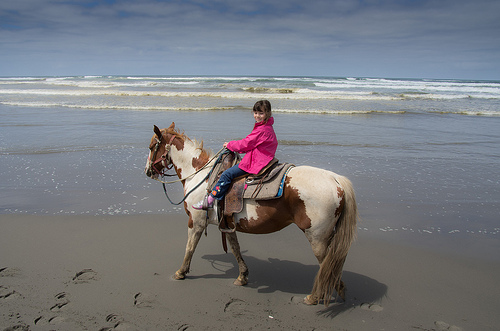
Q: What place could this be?
A: It is a lake.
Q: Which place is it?
A: It is a lake.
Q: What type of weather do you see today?
A: It is cloudy.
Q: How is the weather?
A: It is cloudy.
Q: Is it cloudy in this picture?
A: Yes, it is cloudy.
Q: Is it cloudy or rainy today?
A: It is cloudy.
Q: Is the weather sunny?
A: No, it is cloudy.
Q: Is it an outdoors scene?
A: Yes, it is outdoors.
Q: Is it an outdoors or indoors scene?
A: It is outdoors.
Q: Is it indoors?
A: No, it is outdoors.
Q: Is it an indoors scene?
A: No, it is outdoors.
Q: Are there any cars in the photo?
A: No, there are no cars.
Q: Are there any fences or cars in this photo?
A: No, there are no cars or fences.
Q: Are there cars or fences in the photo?
A: No, there are no cars or fences.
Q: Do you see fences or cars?
A: No, there are no cars or fences.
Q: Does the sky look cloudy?
A: Yes, the sky is cloudy.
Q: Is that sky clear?
A: No, the sky is cloudy.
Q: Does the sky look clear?
A: No, the sky is cloudy.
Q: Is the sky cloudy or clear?
A: The sky is cloudy.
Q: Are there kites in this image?
A: No, there are no kites.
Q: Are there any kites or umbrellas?
A: No, there are no kites or umbrellas.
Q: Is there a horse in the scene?
A: Yes, there is a horse.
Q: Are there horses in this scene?
A: Yes, there is a horse.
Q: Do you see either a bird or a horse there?
A: Yes, there is a horse.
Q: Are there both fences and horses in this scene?
A: No, there is a horse but no fences.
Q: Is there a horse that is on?
A: Yes, there is a horse that is on.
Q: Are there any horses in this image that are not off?
A: Yes, there is a horse that is on.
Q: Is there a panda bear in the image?
A: No, there are no panda bears.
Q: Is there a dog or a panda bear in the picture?
A: No, there are no panda bears or dogs.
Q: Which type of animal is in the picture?
A: The animal is a horse.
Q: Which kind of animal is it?
A: The animal is a horse.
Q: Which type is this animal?
A: This is a horse.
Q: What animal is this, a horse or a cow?
A: This is a horse.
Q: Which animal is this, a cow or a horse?
A: This is a horse.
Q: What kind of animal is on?
A: The animal is a horse.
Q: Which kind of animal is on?
A: The animal is a horse.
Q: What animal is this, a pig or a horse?
A: This is a horse.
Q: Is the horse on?
A: Yes, the horse is on.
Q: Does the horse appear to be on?
A: Yes, the horse is on.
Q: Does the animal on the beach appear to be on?
A: Yes, the horse is on.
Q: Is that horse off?
A: No, the horse is on.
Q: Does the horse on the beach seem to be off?
A: No, the horse is on.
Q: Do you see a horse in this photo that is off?
A: No, there is a horse but it is on.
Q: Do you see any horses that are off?
A: No, there is a horse but it is on.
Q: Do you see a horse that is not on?
A: No, there is a horse but it is on.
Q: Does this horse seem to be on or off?
A: The horse is on.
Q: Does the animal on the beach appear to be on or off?
A: The horse is on.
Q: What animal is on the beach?
A: The horse is on the beach.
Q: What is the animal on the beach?
A: The animal is a horse.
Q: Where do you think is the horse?
A: The horse is on the beach.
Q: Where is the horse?
A: The horse is on the beach.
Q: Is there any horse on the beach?
A: Yes, there is a horse on the beach.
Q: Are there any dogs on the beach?
A: No, there is a horse on the beach.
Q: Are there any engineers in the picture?
A: No, there are no engineers.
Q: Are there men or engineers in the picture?
A: No, there are no engineers or men.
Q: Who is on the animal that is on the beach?
A: The girl is on the horse.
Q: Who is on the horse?
A: The girl is on the horse.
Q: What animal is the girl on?
A: The girl is on the horse.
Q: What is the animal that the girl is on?
A: The animal is a horse.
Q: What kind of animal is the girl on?
A: The girl is on the horse.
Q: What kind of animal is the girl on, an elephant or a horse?
A: The girl is on a horse.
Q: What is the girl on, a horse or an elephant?
A: The girl is on a horse.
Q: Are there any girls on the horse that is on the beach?
A: Yes, there is a girl on the horse.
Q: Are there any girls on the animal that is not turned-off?
A: Yes, there is a girl on the horse.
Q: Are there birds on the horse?
A: No, there is a girl on the horse.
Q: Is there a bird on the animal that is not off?
A: No, there is a girl on the horse.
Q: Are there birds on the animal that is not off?
A: No, there is a girl on the horse.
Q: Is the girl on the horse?
A: Yes, the girl is on the horse.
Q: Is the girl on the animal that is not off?
A: Yes, the girl is on the horse.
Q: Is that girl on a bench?
A: No, the girl is on the horse.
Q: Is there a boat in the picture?
A: No, there are no boats.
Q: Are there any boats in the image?
A: No, there are no boats.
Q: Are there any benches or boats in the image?
A: No, there are no boats or benches.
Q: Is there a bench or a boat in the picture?
A: No, there are no boats or benches.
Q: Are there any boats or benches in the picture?
A: No, there are no boats or benches.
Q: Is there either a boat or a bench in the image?
A: No, there are no boats or benches.